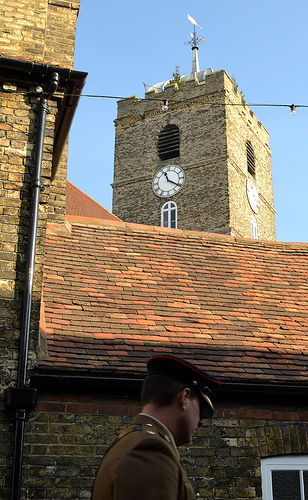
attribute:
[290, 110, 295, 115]
lightbulb — clear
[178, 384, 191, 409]
ear — man's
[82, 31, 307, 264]
tower — brown 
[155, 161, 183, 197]
clock — white 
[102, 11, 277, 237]
tower — tall, brick